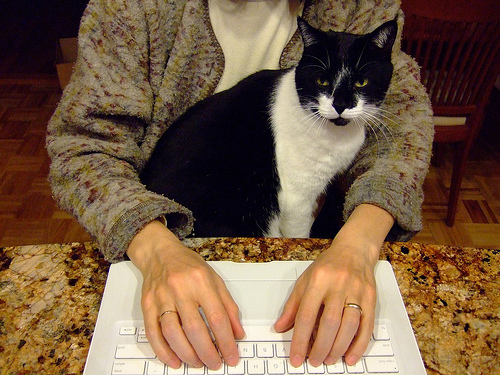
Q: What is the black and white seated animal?
A: Cat.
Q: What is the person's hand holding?
A: Cat.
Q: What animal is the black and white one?
A: Cat.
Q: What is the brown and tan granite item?
A: Table.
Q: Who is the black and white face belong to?
A: Cat.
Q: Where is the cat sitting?
A: Person's lap.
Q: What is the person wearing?
A: Gray sweater.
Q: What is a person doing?
A: Typing on laptop.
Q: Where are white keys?
A: On laptop keyboard.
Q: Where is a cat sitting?
A: On person's lap.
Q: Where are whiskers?
A: On cat's face.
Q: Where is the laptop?
A: On granite countertop.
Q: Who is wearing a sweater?
A: The person.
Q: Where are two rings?
A: Around two fingers.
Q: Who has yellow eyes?
A: The cat.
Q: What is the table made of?
A: Marble.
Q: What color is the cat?
A: Black and white.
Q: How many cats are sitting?
A: 1.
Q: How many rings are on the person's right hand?
A: 1.